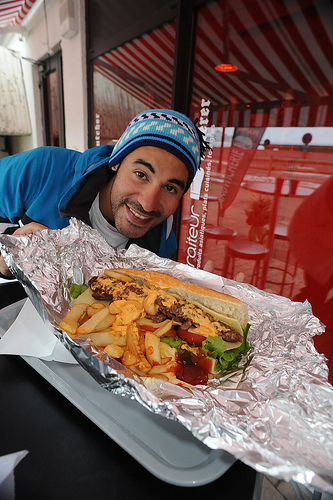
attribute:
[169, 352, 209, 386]
ketchup — red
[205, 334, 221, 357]
lettuce — green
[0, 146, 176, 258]
jacket — blue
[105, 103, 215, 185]
beanie — blue, white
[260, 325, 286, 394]
plate — rectangular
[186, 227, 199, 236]
e — white, letter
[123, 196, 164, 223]
mustache — black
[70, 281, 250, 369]
lettuce — crunchy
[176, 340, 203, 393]
bbq sauce — gyro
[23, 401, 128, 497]
table — black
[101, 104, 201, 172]
hat — blue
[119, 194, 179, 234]
teeth — white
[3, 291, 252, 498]
food tray — white